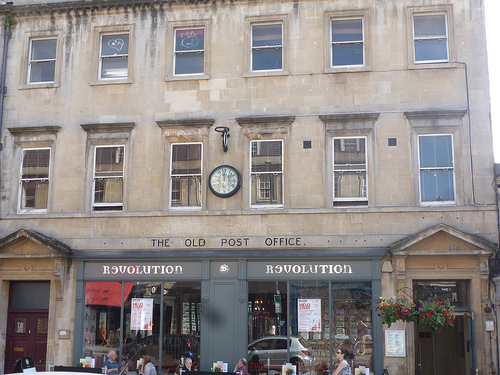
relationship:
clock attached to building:
[205, 163, 237, 198] [1, 15, 488, 240]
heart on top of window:
[102, 39, 125, 53] [235, 11, 290, 74]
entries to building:
[85, 260, 333, 372] [1, 15, 488, 240]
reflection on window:
[231, 276, 297, 328] [235, 11, 290, 74]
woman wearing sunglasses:
[327, 338, 351, 374] [337, 350, 345, 356]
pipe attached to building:
[202, 115, 234, 153] [1, 15, 488, 240]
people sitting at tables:
[77, 343, 357, 371] [219, 364, 279, 372]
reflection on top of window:
[231, 276, 297, 328] [235, 11, 290, 74]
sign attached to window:
[100, 64, 126, 83] [235, 11, 290, 74]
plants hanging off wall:
[360, 303, 417, 333] [192, 78, 274, 108]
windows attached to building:
[49, 41, 418, 83] [1, 15, 488, 240]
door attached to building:
[104, 321, 165, 349] [1, 15, 488, 240]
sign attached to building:
[100, 64, 126, 83] [1, 15, 488, 240]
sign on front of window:
[100, 64, 126, 83] [235, 11, 290, 74]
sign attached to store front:
[100, 64, 126, 83] [178, 237, 251, 316]